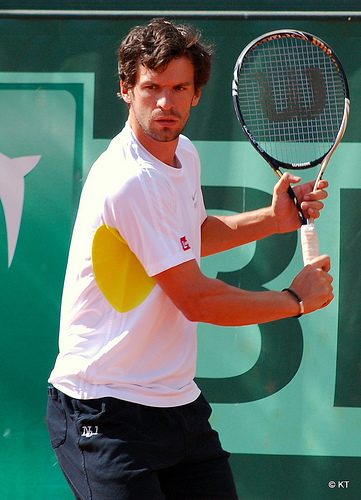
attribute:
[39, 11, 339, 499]
man — playing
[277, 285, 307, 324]
bracelet — black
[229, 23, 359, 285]
racket — black, white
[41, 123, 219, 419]
t-shirt — white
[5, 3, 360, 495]
wall — green, white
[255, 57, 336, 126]
w — wilson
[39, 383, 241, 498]
bottoms — black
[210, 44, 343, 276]
racket — black, white